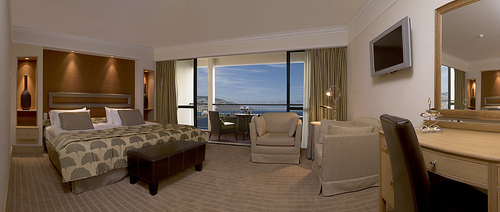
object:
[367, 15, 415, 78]
television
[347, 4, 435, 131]
wall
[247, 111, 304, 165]
chair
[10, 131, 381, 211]
floor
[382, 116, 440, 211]
chair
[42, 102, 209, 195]
bed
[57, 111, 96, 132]
pillows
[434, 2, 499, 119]
mirror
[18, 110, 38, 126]
shelf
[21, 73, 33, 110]
vase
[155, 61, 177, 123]
curtains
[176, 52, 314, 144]
window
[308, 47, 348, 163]
curtains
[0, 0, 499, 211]
room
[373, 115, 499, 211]
desk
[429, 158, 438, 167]
handle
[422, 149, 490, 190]
drawer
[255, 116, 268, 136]
pillow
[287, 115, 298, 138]
pillow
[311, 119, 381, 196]
couch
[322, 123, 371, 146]
pillows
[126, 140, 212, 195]
bench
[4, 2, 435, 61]
ceiling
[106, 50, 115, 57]
lights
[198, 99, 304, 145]
balcony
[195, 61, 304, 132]
view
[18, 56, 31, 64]
light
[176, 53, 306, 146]
doors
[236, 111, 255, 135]
table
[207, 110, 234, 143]
chair